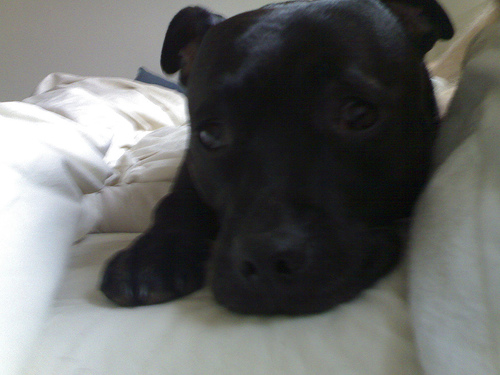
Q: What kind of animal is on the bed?
A: A dog.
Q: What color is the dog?
A: Black.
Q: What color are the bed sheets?
A: White.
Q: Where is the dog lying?
A: On a bed.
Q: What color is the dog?
A: Black.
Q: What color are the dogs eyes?
A: Black.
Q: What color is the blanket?
A: White.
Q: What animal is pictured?
A: A dog.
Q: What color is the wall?
A: Grey.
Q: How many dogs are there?
A: One.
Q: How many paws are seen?
A: One.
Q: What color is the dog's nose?
A: Black.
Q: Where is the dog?
A: On a bed.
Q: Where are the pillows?
A: On the bed.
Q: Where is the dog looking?
A: At the camera.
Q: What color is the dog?
A: Black.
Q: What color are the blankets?
A: White.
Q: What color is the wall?
A: White.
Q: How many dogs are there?
A: One.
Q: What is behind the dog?
A: A wall.